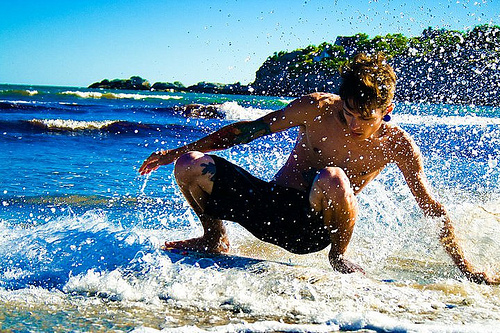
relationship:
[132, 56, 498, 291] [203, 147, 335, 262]
boy has shorts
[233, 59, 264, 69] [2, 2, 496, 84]
clouds in sky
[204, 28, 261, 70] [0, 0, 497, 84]
white clouds in blue sky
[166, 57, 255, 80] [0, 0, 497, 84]
white clouds in blue sky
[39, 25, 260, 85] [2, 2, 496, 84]
clouds in sky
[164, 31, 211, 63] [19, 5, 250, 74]
clouds in sky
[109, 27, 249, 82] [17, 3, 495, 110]
clouds in sky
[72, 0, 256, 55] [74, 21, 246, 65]
clouds in sky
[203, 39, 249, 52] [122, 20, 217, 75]
clouds in sky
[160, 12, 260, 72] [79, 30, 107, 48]
clouds in sky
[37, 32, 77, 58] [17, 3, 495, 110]
clouds in sky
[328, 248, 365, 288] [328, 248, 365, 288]
foot that is visible foot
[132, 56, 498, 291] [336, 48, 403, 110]
boy has brown hair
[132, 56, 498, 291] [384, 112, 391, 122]
boy has ear lobe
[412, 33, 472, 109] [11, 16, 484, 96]
trees in background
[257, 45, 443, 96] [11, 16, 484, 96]
trees in background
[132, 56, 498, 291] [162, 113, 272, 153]
boy has tattoos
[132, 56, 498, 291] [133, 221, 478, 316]
boy is riding a board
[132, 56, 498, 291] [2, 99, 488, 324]
boy is on the water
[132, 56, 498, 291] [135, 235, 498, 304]
boy is on a board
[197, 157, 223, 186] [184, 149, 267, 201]
tattoo on thigh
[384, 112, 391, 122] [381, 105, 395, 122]
ear lobe in his ear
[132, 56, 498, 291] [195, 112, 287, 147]
boy has tattoo